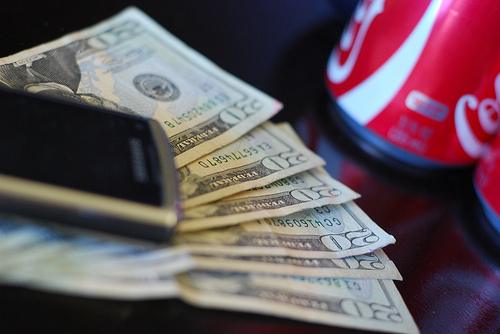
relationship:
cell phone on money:
[2, 74, 182, 249] [3, 8, 425, 333]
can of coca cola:
[320, 7, 484, 167] [313, 1, 498, 181]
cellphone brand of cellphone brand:
[131, 137, 153, 183] [131, 132, 153, 183]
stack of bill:
[0, 5, 417, 332] [1, 5, 283, 168]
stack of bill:
[0, 5, 417, 332] [178, 122, 327, 216]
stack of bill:
[0, 5, 417, 332] [3, 166, 360, 237]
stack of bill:
[0, 5, 417, 332] [5, 202, 397, 259]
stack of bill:
[0, 5, 417, 332] [1, 247, 406, 281]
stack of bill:
[0, 5, 417, 332] [2, 280, 417, 332]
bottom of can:
[326, 77, 451, 167] [284, 3, 498, 206]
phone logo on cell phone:
[127, 134, 154, 207] [4, 87, 179, 242]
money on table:
[3, 8, 425, 333] [6, 9, 485, 327]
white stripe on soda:
[326, 2, 453, 124] [302, 2, 497, 222]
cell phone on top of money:
[0, 85, 182, 243] [3, 8, 425, 333]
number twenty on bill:
[209, 98, 271, 128] [29, 4, 403, 286]